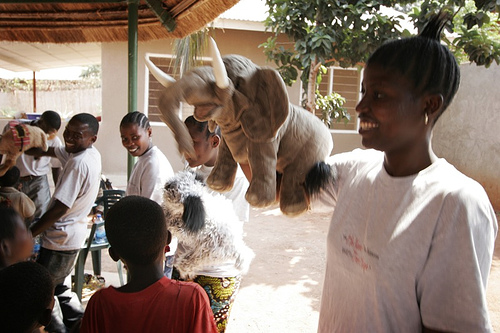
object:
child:
[78, 194, 217, 332]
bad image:
[27, 149, 95, 251]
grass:
[1, 1, 244, 42]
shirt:
[77, 280, 219, 332]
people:
[0, 34, 498, 330]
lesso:
[200, 274, 242, 331]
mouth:
[194, 98, 217, 123]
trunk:
[157, 81, 201, 161]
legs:
[208, 137, 312, 217]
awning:
[1, 0, 249, 44]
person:
[234, 31, 494, 328]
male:
[30, 113, 102, 315]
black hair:
[366, 7, 460, 121]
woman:
[95, 99, 188, 192]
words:
[339, 235, 381, 271]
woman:
[238, 32, 498, 329]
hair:
[68, 113, 100, 138]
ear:
[425, 91, 445, 116]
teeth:
[359, 119, 381, 134]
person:
[88, 109, 199, 231]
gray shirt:
[126, 147, 182, 207]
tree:
[258, 0, 499, 127]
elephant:
[144, 35, 336, 217]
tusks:
[140, 37, 230, 89]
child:
[0, 207, 57, 330]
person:
[27, 110, 105, 332]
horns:
[144, 56, 178, 89]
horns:
[205, 36, 230, 89]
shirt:
[321, 147, 498, 332]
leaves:
[294, 14, 329, 64]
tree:
[274, 0, 496, 59]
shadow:
[234, 203, 335, 311]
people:
[110, 111, 173, 281]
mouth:
[358, 117, 382, 134]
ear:
[235, 68, 291, 145]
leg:
[244, 139, 278, 209]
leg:
[277, 164, 311, 218]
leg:
[207, 143, 237, 192]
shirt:
[39, 143, 104, 252]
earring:
[424, 113, 429, 125]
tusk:
[141, 53, 171, 83]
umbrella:
[6, 3, 235, 70]